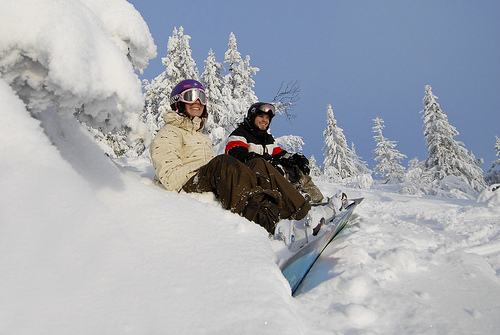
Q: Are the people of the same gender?
A: No, they are both male and female.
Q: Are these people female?
A: No, they are both male and female.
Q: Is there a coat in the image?
A: Yes, there is a coat.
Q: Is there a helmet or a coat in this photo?
A: Yes, there is a coat.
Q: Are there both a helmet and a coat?
A: Yes, there are both a coat and a helmet.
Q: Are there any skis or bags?
A: No, there are no skis or bags.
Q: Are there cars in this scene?
A: No, there are no cars.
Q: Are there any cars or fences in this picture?
A: No, there are no cars or fences.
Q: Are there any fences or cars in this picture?
A: No, there are no cars or fences.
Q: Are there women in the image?
A: Yes, there is a woman.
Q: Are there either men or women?
A: Yes, there is a woman.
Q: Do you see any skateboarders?
A: No, there are no skateboarders.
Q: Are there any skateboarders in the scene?
A: No, there are no skateboarders.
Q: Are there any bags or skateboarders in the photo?
A: No, there are no skateboarders or bags.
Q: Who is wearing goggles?
A: The woman is wearing goggles.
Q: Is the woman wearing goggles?
A: Yes, the woman is wearing goggles.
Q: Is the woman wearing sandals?
A: No, the woman is wearing goggles.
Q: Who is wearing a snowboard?
A: The woman is wearing a snowboard.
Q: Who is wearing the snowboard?
A: The woman is wearing a snowboard.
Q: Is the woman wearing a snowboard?
A: Yes, the woman is wearing a snowboard.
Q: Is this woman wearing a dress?
A: No, the woman is wearing a snowboard.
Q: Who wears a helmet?
A: The woman wears a helmet.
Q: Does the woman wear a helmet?
A: Yes, the woman wears a helmet.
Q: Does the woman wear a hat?
A: No, the woman wears a helmet.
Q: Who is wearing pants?
A: The woman is wearing pants.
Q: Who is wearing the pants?
A: The woman is wearing pants.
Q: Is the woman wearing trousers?
A: Yes, the woman is wearing trousers.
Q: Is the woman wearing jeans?
A: No, the woman is wearing trousers.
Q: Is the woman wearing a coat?
A: Yes, the woman is wearing a coat.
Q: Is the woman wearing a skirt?
A: No, the woman is wearing a coat.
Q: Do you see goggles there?
A: Yes, there are goggles.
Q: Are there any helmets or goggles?
A: Yes, there are goggles.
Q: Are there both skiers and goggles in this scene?
A: No, there are goggles but no skiers.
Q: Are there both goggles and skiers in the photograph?
A: No, there are goggles but no skiers.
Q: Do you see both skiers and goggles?
A: No, there are goggles but no skiers.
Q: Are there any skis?
A: No, there are no skis.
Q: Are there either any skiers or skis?
A: No, there are no skis or skiers.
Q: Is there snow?
A: Yes, there is snow.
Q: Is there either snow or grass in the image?
A: Yes, there is snow.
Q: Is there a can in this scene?
A: No, there are no cans.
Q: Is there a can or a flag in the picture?
A: No, there are no cans or flags.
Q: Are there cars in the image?
A: No, there are no cars.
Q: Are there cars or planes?
A: No, there are no cars or planes.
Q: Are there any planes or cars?
A: No, there are no cars or planes.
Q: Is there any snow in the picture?
A: Yes, there is snow.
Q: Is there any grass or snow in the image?
A: Yes, there is snow.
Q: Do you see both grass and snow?
A: No, there is snow but no grass.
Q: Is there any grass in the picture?
A: No, there is no grass.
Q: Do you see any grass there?
A: No, there is no grass.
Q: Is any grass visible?
A: No, there is no grass.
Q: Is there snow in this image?
A: Yes, there is snow.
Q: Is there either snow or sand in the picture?
A: Yes, there is snow.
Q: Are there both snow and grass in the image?
A: No, there is snow but no grass.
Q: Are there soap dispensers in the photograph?
A: No, there are no soap dispensers.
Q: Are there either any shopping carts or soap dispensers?
A: No, there are no soap dispensers or shopping carts.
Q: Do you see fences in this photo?
A: No, there are no fences.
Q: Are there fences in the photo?
A: No, there are no fences.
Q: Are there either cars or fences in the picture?
A: No, there are no fences or cars.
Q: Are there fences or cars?
A: No, there are no fences or cars.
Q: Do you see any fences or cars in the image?
A: No, there are no fences or cars.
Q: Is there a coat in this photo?
A: Yes, there is a coat.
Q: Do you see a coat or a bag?
A: Yes, there is a coat.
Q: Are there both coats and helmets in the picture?
A: Yes, there are both a coat and a helmet.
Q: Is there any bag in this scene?
A: No, there are no bags.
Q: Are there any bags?
A: No, there are no bags.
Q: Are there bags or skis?
A: No, there are no bags or skis.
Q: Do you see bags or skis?
A: No, there are no bags or skis.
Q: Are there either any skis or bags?
A: No, there are no bags or skis.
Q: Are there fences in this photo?
A: No, there are no fences.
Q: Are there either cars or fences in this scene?
A: No, there are no cars or fences.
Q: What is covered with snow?
A: The trees are covered with snow.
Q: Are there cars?
A: No, there are no cars.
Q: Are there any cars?
A: No, there are no cars.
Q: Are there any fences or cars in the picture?
A: No, there are no cars or fences.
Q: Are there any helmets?
A: Yes, there is a helmet.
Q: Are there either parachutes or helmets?
A: Yes, there is a helmet.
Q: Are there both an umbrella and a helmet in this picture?
A: No, there is a helmet but no umbrellas.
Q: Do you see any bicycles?
A: No, there are no bicycles.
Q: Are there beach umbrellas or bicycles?
A: No, there are no bicycles or beach umbrellas.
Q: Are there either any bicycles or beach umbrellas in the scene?
A: No, there are no bicycles or beach umbrellas.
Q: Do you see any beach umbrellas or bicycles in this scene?
A: No, there are no bicycles or beach umbrellas.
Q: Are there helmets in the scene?
A: Yes, there is a helmet.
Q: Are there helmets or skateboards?
A: Yes, there is a helmet.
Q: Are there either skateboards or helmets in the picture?
A: Yes, there is a helmet.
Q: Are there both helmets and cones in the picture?
A: No, there is a helmet but no cones.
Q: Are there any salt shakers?
A: No, there are no salt shakers.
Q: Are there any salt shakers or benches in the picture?
A: No, there are no salt shakers or benches.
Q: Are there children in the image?
A: No, there are no children.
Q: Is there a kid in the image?
A: No, there are no children.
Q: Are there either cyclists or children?
A: No, there are no children or cyclists.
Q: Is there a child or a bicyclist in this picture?
A: No, there are no children or cyclists.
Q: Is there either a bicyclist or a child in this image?
A: No, there are no children or cyclists.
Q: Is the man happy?
A: Yes, the man is happy.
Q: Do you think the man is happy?
A: Yes, the man is happy.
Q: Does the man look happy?
A: Yes, the man is happy.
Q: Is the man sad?
A: No, the man is happy.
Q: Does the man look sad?
A: No, the man is happy.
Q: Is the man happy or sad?
A: The man is happy.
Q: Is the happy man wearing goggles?
A: Yes, the man is wearing goggles.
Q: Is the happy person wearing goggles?
A: Yes, the man is wearing goggles.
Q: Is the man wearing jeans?
A: No, the man is wearing goggles.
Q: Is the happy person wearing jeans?
A: No, the man is wearing goggles.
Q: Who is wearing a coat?
A: The man is wearing a coat.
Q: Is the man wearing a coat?
A: Yes, the man is wearing a coat.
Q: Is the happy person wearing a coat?
A: Yes, the man is wearing a coat.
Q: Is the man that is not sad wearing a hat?
A: No, the man is wearing a coat.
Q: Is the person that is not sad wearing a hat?
A: No, the man is wearing a coat.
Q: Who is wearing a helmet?
A: The man is wearing a helmet.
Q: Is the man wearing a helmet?
A: Yes, the man is wearing a helmet.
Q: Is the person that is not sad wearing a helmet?
A: Yes, the man is wearing a helmet.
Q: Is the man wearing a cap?
A: No, the man is wearing a helmet.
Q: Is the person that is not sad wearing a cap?
A: No, the man is wearing a helmet.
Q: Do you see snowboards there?
A: Yes, there is a snowboard.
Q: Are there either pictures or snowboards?
A: Yes, there is a snowboard.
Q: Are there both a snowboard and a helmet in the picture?
A: Yes, there are both a snowboard and a helmet.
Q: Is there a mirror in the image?
A: No, there are no mirrors.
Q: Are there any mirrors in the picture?
A: No, there are no mirrors.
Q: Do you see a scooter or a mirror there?
A: No, there are no mirrors or scooters.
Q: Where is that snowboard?
A: The snowboard is on the snow.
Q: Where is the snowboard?
A: The snowboard is on the snow.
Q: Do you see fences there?
A: No, there are no fences.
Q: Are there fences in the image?
A: No, there are no fences.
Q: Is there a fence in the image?
A: No, there are no fences.